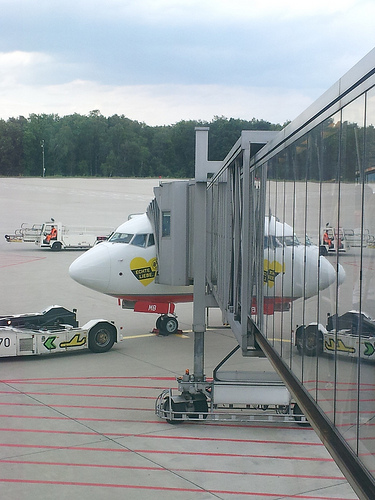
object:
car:
[0, 305, 125, 362]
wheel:
[89, 323, 117, 353]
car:
[320, 221, 364, 256]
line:
[231, 88, 375, 462]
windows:
[262, 234, 304, 248]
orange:
[45, 228, 57, 243]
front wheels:
[155, 368, 209, 425]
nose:
[68, 248, 109, 290]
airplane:
[68, 212, 339, 336]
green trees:
[0, 107, 375, 184]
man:
[44, 225, 57, 248]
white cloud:
[76, 0, 374, 38]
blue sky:
[0, 0, 375, 129]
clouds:
[0, 53, 281, 126]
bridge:
[146, 47, 375, 500]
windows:
[107, 231, 155, 250]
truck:
[3, 219, 111, 252]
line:
[0, 377, 375, 500]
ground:
[0, 173, 375, 500]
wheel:
[155, 313, 178, 334]